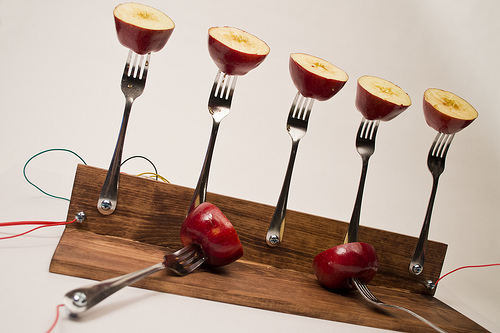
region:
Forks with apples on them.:
[110, 10, 457, 254]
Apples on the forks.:
[61, 146, 271, 311]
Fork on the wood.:
[56, 177, 305, 326]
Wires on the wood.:
[19, 109, 209, 246]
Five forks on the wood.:
[84, 42, 490, 267]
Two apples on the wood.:
[176, 181, 428, 322]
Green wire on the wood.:
[12, 122, 95, 244]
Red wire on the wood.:
[9, 202, 84, 243]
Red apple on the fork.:
[145, 197, 286, 307]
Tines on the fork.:
[112, 24, 175, 111]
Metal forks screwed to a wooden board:
[5, 2, 487, 327]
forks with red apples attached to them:
[13, 6, 491, 320]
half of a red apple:
[106, 0, 181, 55]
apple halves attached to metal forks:
[94, 3, 494, 176]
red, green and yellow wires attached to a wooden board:
[3, 118, 177, 241]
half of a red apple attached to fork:
[309, 231, 408, 331]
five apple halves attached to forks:
[100, 0, 489, 170]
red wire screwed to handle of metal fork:
[8, 242, 101, 332]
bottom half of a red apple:
[104, 2, 183, 52]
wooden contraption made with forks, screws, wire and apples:
[3, 5, 496, 327]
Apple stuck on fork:
[114, 5, 176, 55]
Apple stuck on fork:
[206, 19, 271, 76]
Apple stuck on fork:
[287, 50, 351, 101]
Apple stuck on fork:
[354, 74, 415, 120]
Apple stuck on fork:
[420, 84, 479, 131]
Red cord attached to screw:
[0, 207, 83, 238]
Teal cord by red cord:
[19, 147, 88, 201]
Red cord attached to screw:
[425, 255, 499, 300]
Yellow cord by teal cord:
[140, 166, 170, 186]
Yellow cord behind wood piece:
[139, 171, 172, 185]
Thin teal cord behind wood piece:
[21, 147, 96, 205]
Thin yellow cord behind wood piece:
[135, 172, 179, 191]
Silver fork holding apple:
[92, 44, 155, 214]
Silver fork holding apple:
[185, 67, 237, 217]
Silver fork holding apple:
[260, 90, 315, 241]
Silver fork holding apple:
[337, 111, 377, 251]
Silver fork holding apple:
[405, 130, 455, 275]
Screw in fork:
[100, 195, 110, 210]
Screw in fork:
[266, 228, 279, 241]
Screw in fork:
[411, 259, 426, 273]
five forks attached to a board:
[85, 96, 445, 279]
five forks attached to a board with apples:
[115, 37, 494, 162]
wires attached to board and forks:
[19, 138, 177, 235]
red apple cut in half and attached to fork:
[173, 194, 251, 266]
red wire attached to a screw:
[424, 256, 492, 297]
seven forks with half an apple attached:
[55, 61, 477, 313]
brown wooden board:
[37, 168, 169, 289]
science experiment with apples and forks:
[42, 23, 476, 313]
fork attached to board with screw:
[252, 232, 292, 253]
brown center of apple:
[135, 3, 167, 23]